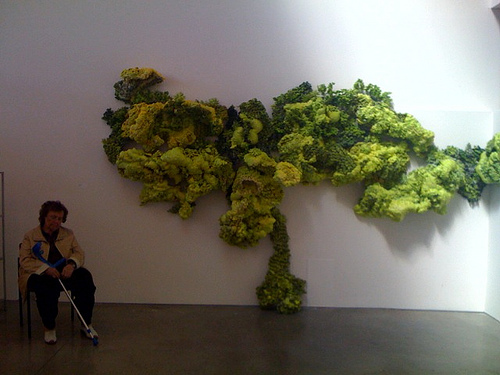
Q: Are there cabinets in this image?
A: No, there are no cabinets.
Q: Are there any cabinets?
A: No, there are no cabinets.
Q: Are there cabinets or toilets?
A: No, there are no cabinets or toilets.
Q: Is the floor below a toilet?
A: No, the floor is below the woman.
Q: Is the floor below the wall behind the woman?
A: Yes, the floor is below the wall.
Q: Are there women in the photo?
A: Yes, there is a woman.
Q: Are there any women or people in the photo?
A: Yes, there is a woman.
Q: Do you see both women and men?
A: No, there is a woman but no men.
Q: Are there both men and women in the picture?
A: No, there is a woman but no men.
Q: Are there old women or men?
A: Yes, there is an old woman.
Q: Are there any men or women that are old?
A: Yes, the woman is old.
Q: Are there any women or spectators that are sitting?
A: Yes, the woman is sitting.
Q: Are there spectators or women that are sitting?
A: Yes, the woman is sitting.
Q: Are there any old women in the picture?
A: Yes, there is an old woman.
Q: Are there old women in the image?
A: Yes, there is an old woman.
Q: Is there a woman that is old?
A: Yes, there is a woman that is old.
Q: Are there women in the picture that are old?
A: Yes, there is a woman that is old.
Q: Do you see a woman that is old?
A: Yes, there is a woman that is old.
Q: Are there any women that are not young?
A: Yes, there is a old woman.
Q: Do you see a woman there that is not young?
A: Yes, there is a old woman.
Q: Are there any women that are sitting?
A: Yes, there is a woman that is sitting.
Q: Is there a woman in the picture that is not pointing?
A: Yes, there is a woman that is sitting.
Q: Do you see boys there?
A: No, there are no boys.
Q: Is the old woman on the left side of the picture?
A: Yes, the woman is on the left of the image.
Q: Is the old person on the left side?
A: Yes, the woman is on the left of the image.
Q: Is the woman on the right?
A: No, the woman is on the left of the image.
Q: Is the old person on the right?
A: No, the woman is on the left of the image.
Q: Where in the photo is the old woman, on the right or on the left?
A: The woman is on the left of the image.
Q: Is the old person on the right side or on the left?
A: The woman is on the left of the image.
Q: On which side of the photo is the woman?
A: The woman is on the left of the image.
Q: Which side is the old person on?
A: The woman is on the left of the image.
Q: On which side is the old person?
A: The woman is on the left of the image.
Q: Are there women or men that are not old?
A: No, there is a woman but she is old.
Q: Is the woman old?
A: Yes, the woman is old.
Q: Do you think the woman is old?
A: Yes, the woman is old.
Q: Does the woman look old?
A: Yes, the woman is old.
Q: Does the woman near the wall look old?
A: Yes, the woman is old.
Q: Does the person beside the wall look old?
A: Yes, the woman is old.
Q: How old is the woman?
A: The woman is old.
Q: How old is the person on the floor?
A: The woman is old.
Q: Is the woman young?
A: No, the woman is old.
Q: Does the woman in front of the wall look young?
A: No, the woman is old.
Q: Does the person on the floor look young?
A: No, the woman is old.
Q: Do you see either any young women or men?
A: No, there is a woman but she is old.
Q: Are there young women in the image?
A: No, there is a woman but she is old.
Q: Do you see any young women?
A: No, there is a woman but she is old.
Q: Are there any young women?
A: No, there is a woman but she is old.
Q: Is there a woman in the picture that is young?
A: No, there is a woman but she is old.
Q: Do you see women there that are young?
A: No, there is a woman but she is old.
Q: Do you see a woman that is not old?
A: No, there is a woman but she is old.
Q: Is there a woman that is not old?
A: No, there is a woman but she is old.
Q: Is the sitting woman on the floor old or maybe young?
A: The woman is old.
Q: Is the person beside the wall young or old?
A: The woman is old.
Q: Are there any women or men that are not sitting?
A: No, there is a woman but she is sitting.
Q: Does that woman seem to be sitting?
A: Yes, the woman is sitting.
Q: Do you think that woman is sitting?
A: Yes, the woman is sitting.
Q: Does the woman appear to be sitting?
A: Yes, the woman is sitting.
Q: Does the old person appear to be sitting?
A: Yes, the woman is sitting.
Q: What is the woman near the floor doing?
A: The woman is sitting.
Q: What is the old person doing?
A: The woman is sitting.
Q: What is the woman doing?
A: The woman is sitting.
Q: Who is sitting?
A: The woman is sitting.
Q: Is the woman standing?
A: No, the woman is sitting.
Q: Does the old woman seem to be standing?
A: No, the woman is sitting.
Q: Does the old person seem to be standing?
A: No, the woman is sitting.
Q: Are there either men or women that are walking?
A: No, there is a woman but she is sitting.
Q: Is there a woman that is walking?
A: No, there is a woman but she is sitting.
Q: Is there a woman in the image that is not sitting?
A: No, there is a woman but she is sitting.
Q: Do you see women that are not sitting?
A: No, there is a woman but she is sitting.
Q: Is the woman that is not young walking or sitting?
A: The woman is sitting.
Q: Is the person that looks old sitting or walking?
A: The woman is sitting.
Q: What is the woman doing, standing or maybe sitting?
A: The woman is sitting.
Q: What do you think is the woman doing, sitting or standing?
A: The woman is sitting.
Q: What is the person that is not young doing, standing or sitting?
A: The woman is sitting.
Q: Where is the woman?
A: The woman is on the floor.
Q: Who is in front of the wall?
A: The woman is in front of the wall.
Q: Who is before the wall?
A: The woman is in front of the wall.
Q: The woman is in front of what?
A: The woman is in front of the wall.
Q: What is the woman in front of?
A: The woman is in front of the wall.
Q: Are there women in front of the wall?
A: Yes, there is a woman in front of the wall.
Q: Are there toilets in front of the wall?
A: No, there is a woman in front of the wall.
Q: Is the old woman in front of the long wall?
A: Yes, the woman is in front of the wall.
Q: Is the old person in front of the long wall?
A: Yes, the woman is in front of the wall.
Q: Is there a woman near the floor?
A: Yes, there is a woman near the floor.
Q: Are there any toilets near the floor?
A: No, there is a woman near the floor.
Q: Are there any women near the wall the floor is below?
A: Yes, there is a woman near the wall.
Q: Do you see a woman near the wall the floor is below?
A: Yes, there is a woman near the wall.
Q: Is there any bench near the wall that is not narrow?
A: No, there is a woman near the wall.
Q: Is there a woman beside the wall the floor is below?
A: Yes, there is a woman beside the wall.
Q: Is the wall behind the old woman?
A: Yes, the wall is behind the woman.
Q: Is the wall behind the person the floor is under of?
A: Yes, the wall is behind the woman.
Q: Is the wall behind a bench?
A: No, the wall is behind the woman.